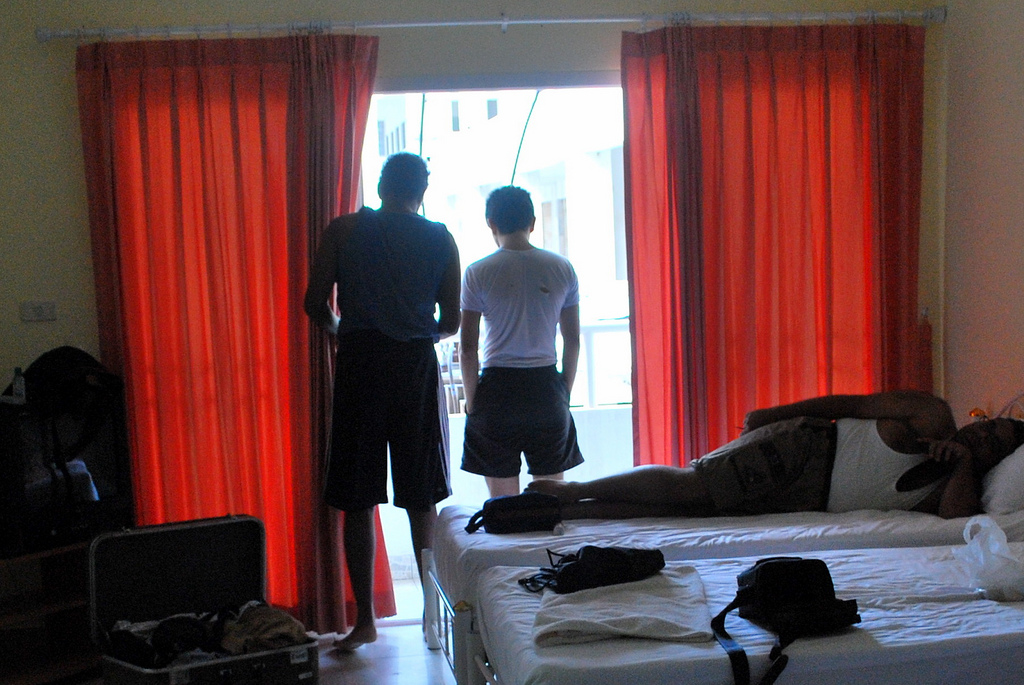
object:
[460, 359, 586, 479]
shorts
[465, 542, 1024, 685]
bed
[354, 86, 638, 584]
door way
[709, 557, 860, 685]
bag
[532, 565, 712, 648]
towel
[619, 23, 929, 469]
curtain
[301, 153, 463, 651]
man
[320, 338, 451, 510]
shorts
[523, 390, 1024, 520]
man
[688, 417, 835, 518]
shorts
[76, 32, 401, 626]
curtain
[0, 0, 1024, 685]
building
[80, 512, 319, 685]
suitcase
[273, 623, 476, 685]
floor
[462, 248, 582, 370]
shirt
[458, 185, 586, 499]
man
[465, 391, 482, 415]
hands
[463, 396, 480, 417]
pockets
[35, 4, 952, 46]
rod